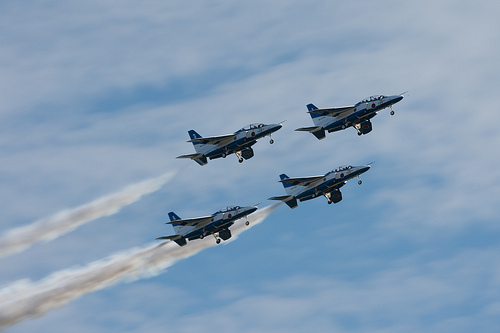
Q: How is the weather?
A: It is cloudy.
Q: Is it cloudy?
A: Yes, it is cloudy.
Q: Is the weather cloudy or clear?
A: It is cloudy.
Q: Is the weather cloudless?
A: No, it is cloudy.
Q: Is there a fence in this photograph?
A: No, there are no fences.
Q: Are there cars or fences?
A: No, there are no fences or cars.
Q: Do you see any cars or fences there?
A: No, there are no fences or cars.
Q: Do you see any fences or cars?
A: No, there are no fences or cars.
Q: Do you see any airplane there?
A: Yes, there is an airplane.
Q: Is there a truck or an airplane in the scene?
A: Yes, there is an airplane.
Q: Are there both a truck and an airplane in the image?
A: No, there is an airplane but no trucks.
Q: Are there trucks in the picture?
A: No, there are no trucks.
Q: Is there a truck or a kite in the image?
A: No, there are no trucks or kites.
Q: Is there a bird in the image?
A: No, there are no birds.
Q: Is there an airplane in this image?
A: Yes, there is an airplane.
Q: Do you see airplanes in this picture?
A: Yes, there is an airplane.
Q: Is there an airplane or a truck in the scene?
A: Yes, there is an airplane.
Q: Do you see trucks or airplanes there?
A: Yes, there is an airplane.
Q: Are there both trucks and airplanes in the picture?
A: No, there is an airplane but no trucks.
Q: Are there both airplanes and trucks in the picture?
A: No, there is an airplane but no trucks.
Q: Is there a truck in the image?
A: No, there are no trucks.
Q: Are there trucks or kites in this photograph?
A: No, there are no trucks or kites.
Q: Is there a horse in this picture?
A: No, there are no horses.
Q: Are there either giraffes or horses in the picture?
A: No, there are no horses or giraffes.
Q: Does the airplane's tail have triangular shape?
A: Yes, the tail is triangular.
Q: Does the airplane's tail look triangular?
A: Yes, the tail is triangular.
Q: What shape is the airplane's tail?
A: The tail is triangular.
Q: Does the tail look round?
A: No, the tail is triangular.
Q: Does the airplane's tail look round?
A: No, the tail is triangular.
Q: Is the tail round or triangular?
A: The tail is triangular.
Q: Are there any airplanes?
A: Yes, there is an airplane.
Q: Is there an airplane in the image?
A: Yes, there is an airplane.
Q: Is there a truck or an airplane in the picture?
A: Yes, there is an airplane.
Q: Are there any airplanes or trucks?
A: Yes, there is an airplane.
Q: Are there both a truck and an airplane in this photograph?
A: No, there is an airplane but no trucks.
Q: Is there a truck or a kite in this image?
A: No, there are no kites or trucks.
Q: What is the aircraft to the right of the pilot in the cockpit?
A: The aircraft is an airplane.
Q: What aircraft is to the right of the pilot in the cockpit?
A: The aircraft is an airplane.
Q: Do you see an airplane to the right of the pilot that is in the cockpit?
A: Yes, there is an airplane to the right of the pilot.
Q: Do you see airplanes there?
A: Yes, there is an airplane.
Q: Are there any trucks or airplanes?
A: Yes, there is an airplane.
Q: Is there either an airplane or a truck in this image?
A: Yes, there is an airplane.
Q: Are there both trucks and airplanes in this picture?
A: No, there is an airplane but no trucks.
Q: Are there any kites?
A: No, there are no kites.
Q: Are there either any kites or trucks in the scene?
A: No, there are no kites or trucks.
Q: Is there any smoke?
A: Yes, there is smoke.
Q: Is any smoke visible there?
A: Yes, there is smoke.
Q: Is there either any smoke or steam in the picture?
A: Yes, there is smoke.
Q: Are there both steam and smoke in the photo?
A: No, there is smoke but no steam.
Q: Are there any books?
A: No, there are no books.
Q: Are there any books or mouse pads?
A: No, there are no books or mouse pads.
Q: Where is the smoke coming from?
A: The smoke is coming from the airplane.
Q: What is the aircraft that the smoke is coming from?
A: The aircraft is an airplane.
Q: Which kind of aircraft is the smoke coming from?
A: The smoke is coming from the plane.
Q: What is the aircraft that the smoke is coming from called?
A: The aircraft is an airplane.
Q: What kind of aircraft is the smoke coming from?
A: The smoke is coming from the airplane.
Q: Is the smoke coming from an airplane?
A: Yes, the smoke is coming from an airplane.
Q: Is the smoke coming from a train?
A: No, the smoke is coming from an airplane.